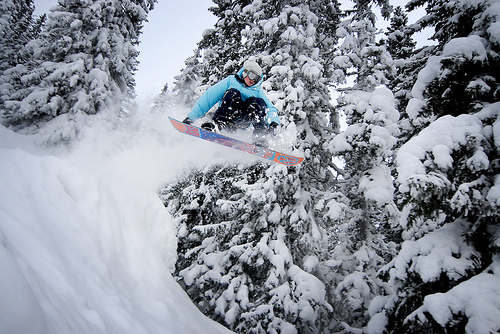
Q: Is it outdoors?
A: Yes, it is outdoors.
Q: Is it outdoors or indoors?
A: It is outdoors.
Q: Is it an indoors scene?
A: No, it is outdoors.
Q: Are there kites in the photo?
A: No, there are no kites.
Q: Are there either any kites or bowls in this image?
A: No, there are no kites or bowls.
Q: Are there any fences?
A: No, there are no fences.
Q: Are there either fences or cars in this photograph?
A: No, there are no fences or cars.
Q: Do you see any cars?
A: No, there are no cars.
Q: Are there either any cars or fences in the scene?
A: No, there are no cars or fences.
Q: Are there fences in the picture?
A: No, there are no fences.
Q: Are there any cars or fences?
A: No, there are no fences or cars.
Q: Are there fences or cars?
A: No, there are no fences or cars.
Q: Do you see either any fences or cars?
A: No, there are no fences or cars.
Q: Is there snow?
A: Yes, there is snow.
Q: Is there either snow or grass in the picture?
A: Yes, there is snow.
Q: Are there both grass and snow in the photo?
A: No, there is snow but no grass.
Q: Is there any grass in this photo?
A: No, there is no grass.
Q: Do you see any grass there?
A: No, there is no grass.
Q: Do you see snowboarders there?
A: Yes, there is a snowboarder.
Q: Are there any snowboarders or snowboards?
A: Yes, there is a snowboarder.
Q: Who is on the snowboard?
A: The snowboarder is on the snowboard.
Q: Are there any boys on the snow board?
A: No, there is a snowboarder on the snow board.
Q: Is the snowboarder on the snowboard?
A: Yes, the snowboarder is on the snowboard.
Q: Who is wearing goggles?
A: The snowboarder is wearing goggles.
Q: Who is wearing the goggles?
A: The snowboarder is wearing goggles.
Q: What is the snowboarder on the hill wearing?
A: The snowboarder is wearing goggles.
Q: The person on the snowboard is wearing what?
A: The snowboarder is wearing goggles.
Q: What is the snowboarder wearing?
A: The snowboarder is wearing goggles.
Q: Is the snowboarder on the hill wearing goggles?
A: Yes, the snowboarder is wearing goggles.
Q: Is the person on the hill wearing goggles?
A: Yes, the snowboarder is wearing goggles.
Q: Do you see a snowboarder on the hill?
A: Yes, there is a snowboarder on the hill.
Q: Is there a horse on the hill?
A: No, there is a snowboarder on the hill.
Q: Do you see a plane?
A: No, there are no airplanes.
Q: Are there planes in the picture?
A: No, there are no planes.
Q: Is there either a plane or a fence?
A: No, there are no airplanes or fences.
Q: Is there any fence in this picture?
A: No, there are no fences.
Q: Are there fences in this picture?
A: No, there are no fences.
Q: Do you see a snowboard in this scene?
A: Yes, there is a snowboard.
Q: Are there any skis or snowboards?
A: Yes, there is a snowboard.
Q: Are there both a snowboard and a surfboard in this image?
A: No, there is a snowboard but no surfboards.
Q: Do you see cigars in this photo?
A: No, there are no cigars.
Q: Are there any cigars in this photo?
A: No, there are no cigars.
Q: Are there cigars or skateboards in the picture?
A: No, there are no cigars or skateboards.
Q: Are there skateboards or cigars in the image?
A: No, there are no cigars or skateboards.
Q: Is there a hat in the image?
A: Yes, there is a hat.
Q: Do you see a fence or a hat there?
A: Yes, there is a hat.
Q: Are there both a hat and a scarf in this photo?
A: No, there is a hat but no scarves.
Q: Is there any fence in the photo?
A: No, there are no fences.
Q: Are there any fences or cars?
A: No, there are no fences or cars.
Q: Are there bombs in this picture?
A: No, there are no bombs.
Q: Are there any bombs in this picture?
A: No, there are no bombs.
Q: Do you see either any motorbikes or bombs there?
A: No, there are no bombs or motorbikes.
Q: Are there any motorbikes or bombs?
A: No, there are no bombs or motorbikes.